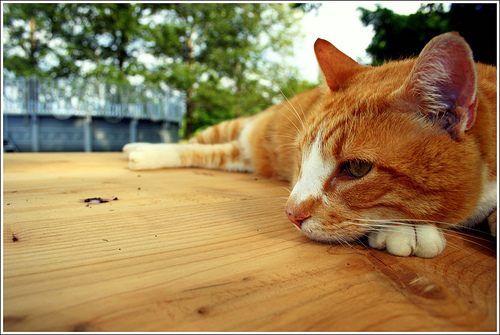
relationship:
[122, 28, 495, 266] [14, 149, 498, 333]
cat laying on table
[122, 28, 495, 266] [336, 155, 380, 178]
cat has eye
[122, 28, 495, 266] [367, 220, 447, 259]
cat has foot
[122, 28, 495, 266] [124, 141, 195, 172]
cat has foot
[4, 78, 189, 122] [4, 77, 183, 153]
fence around above ground pool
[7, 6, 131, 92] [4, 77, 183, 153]
shade tree above above ground pool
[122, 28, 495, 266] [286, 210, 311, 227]
cat has nose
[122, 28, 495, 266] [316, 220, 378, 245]
cat has mouth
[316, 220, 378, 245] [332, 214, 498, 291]
mouth has whiskers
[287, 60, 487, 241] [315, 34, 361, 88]
head has ear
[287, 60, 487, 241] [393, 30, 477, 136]
head has ear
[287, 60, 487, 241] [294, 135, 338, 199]
head has spot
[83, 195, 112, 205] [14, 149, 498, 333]
debris on top of table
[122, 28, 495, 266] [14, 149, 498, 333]
cat on top of table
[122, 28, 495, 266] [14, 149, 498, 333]
cat sits on table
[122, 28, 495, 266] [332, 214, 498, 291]
cat has whiskers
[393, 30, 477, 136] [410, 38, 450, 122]
ear has hair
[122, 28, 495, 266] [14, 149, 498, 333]
cat on table